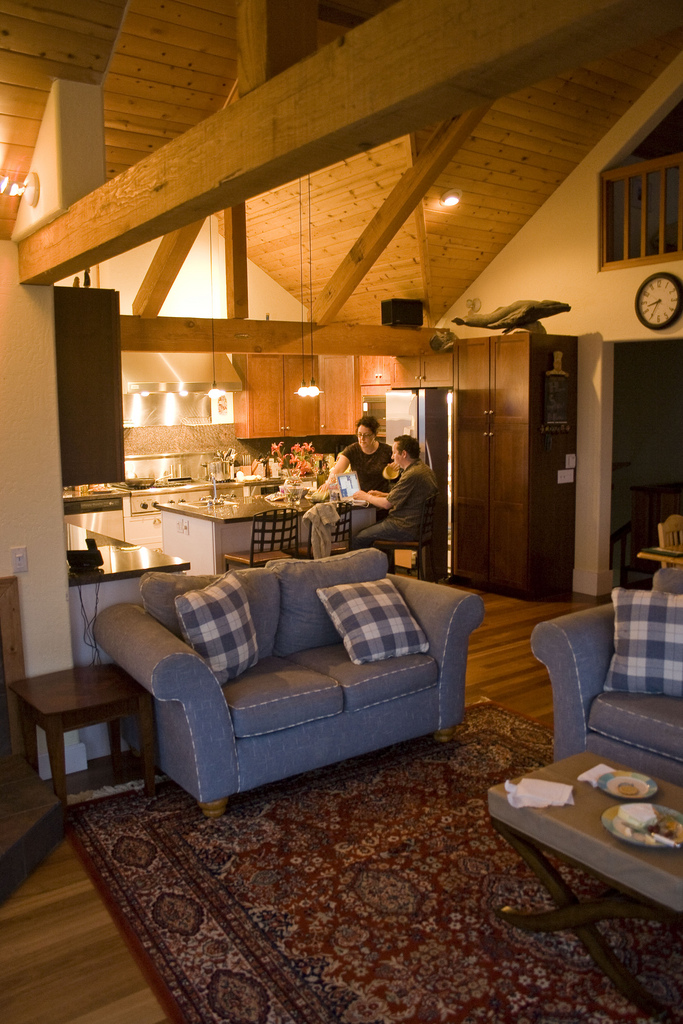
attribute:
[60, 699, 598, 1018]
area rug — maroon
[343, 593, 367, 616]
white square — on a pillow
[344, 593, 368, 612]
white square — on a pillow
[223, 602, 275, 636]
square — white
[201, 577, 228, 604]
square — white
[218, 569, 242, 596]
square — white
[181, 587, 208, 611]
square — white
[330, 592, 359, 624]
square — white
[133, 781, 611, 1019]
rug — red, persian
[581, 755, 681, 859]
plate — colorful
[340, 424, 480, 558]
man — sitting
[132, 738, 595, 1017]
rug — red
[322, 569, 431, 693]
pillow — blue , white 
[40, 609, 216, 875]
table — small 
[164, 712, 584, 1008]
rug — red 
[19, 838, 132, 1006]
floor — wooden 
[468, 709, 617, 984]
table — brown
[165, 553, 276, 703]
pillow — white , blue 